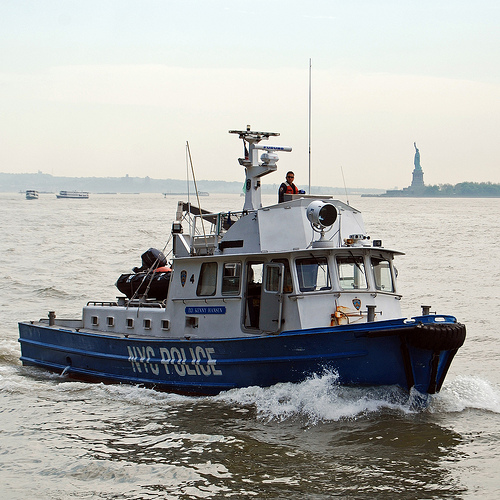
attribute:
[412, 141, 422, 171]
statue — distant, statue of liberty, green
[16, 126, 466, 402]
boat — metal, moving, patrolling, gliding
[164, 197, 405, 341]
cabin — white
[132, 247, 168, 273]
motor — black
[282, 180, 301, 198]
vest — orange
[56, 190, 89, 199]
boat — distant, ferry, moving, white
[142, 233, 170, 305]
rope — tied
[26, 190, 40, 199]
ferry — distant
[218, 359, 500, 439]
wave — splashing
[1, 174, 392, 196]
skyline — distant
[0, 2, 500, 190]
sky — clear, pale